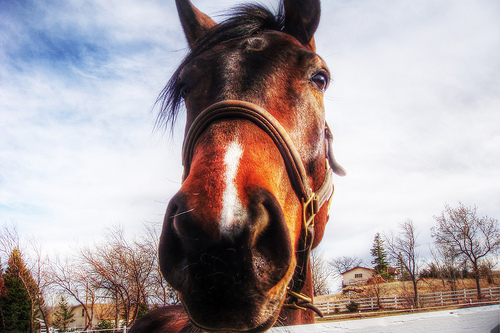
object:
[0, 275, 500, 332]
pasture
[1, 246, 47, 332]
trees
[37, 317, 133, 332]
barn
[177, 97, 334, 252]
horse's bridle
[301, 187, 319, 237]
buckle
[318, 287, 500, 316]
fence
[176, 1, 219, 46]
ear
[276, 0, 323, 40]
ear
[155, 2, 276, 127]
hair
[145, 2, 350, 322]
face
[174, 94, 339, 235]
gear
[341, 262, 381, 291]
house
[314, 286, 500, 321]
railing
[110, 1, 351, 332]
horse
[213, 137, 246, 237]
patch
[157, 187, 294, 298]
nose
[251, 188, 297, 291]
nostril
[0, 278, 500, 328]
hill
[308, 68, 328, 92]
eye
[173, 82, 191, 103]
eye